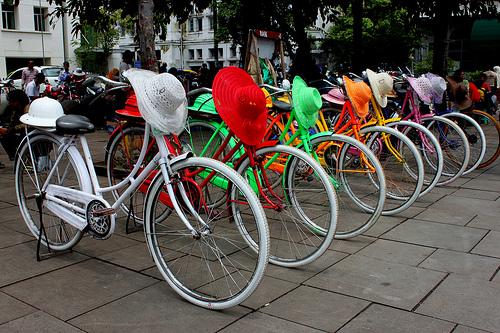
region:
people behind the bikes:
[8, 43, 151, 95]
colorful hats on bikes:
[115, 45, 450, 150]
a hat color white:
[117, 61, 192, 143]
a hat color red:
[206, 62, 276, 147]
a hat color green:
[287, 70, 319, 126]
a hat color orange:
[338, 68, 374, 118]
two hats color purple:
[400, 62, 448, 107]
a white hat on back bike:
[13, 87, 74, 137]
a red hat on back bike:
[116, 92, 141, 128]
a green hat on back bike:
[188, 85, 215, 119]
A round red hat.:
[211, 66, 271, 144]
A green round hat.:
[287, 73, 322, 131]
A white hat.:
[124, 60, 189, 135]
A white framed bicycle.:
[8, 80, 279, 322]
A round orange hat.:
[340, 73, 372, 118]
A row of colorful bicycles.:
[7, 65, 494, 303]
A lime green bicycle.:
[177, 90, 390, 252]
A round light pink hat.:
[405, 74, 435, 106]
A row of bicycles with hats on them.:
[20, 70, 497, 315]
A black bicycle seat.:
[50, 110, 96, 135]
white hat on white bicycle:
[122, 68, 189, 136]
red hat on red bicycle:
[210, 67, 267, 146]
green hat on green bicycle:
[292, 75, 324, 126]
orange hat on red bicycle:
[341, 75, 370, 116]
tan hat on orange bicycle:
[367, 71, 393, 106]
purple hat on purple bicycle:
[405, 72, 432, 103]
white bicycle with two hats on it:
[11, 67, 271, 313]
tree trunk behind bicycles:
[135, 1, 161, 72]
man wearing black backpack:
[444, 71, 479, 150]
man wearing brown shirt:
[448, 71, 477, 142]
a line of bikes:
[21, 58, 493, 311]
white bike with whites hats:
[10, 58, 275, 320]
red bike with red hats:
[114, 54, 281, 151]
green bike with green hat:
[282, 73, 335, 150]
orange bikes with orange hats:
[329, 75, 401, 147]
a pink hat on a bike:
[400, 68, 435, 115]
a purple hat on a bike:
[433, 69, 463, 121]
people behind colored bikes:
[11, 51, 121, 130]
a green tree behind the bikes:
[88, 2, 255, 127]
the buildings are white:
[7, 3, 322, 70]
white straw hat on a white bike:
[121, 67, 187, 130]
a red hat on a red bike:
[210, 65, 268, 145]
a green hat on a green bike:
[290, 72, 320, 128]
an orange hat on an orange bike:
[340, 75, 367, 115]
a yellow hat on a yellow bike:
[365, 65, 391, 105]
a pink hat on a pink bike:
[405, 75, 430, 100]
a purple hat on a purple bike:
[425, 70, 445, 97]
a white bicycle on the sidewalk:
[13, 68, 269, 308]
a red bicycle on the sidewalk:
[105, 65, 337, 267]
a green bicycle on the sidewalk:
[186, 75, 387, 238]